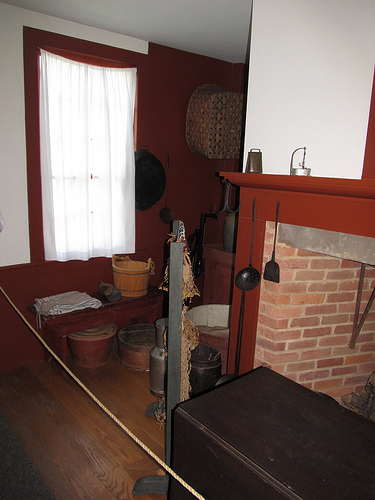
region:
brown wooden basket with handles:
[112, 253, 154, 303]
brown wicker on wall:
[186, 81, 243, 164]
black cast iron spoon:
[238, 198, 263, 292]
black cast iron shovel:
[267, 201, 281, 296]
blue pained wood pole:
[135, 225, 183, 499]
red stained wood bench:
[34, 279, 165, 369]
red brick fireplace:
[254, 215, 374, 431]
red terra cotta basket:
[66, 327, 121, 375]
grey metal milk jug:
[151, 319, 171, 396]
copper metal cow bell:
[245, 146, 264, 177]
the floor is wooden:
[41, 455, 68, 487]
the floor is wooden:
[95, 454, 105, 469]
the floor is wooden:
[95, 443, 110, 469]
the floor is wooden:
[80, 445, 97, 466]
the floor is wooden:
[66, 431, 99, 458]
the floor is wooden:
[74, 447, 93, 463]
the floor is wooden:
[95, 461, 140, 493]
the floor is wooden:
[88, 468, 107, 486]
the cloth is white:
[22, 272, 127, 394]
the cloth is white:
[40, 286, 155, 425]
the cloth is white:
[40, 282, 112, 342]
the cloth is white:
[45, 255, 87, 305]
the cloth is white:
[50, 260, 144, 372]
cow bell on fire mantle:
[240, 145, 262, 171]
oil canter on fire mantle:
[285, 142, 309, 174]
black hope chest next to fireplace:
[163, 361, 373, 498]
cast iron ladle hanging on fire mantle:
[237, 192, 261, 293]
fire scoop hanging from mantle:
[262, 196, 283, 283]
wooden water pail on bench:
[108, 250, 158, 300]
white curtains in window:
[33, 44, 142, 266]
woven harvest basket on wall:
[185, 85, 249, 162]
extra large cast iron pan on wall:
[124, 143, 167, 211]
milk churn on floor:
[147, 316, 176, 398]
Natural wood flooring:
[16, 392, 88, 468]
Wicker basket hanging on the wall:
[186, 79, 238, 161]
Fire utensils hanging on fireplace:
[241, 190, 282, 292]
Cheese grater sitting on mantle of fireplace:
[244, 141, 269, 179]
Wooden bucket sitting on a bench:
[107, 254, 157, 297]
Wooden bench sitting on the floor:
[24, 291, 169, 366]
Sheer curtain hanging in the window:
[28, 39, 143, 256]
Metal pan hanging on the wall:
[120, 139, 171, 215]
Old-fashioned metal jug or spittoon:
[148, 314, 180, 399]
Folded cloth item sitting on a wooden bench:
[27, 287, 102, 317]